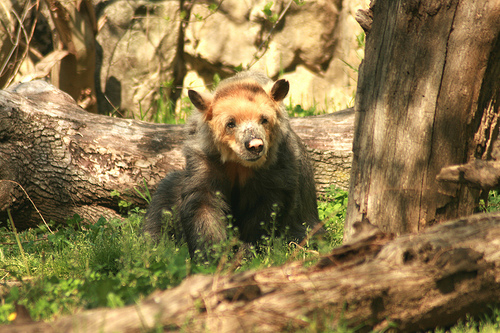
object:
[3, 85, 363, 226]
log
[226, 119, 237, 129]
eye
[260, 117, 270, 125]
eye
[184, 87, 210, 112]
ear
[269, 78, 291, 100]
ear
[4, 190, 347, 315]
grass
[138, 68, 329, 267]
bear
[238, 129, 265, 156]
nose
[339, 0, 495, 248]
tree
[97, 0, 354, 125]
wall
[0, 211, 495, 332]
log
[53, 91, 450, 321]
ground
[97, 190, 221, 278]
weeds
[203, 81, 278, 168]
face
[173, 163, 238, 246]
leg